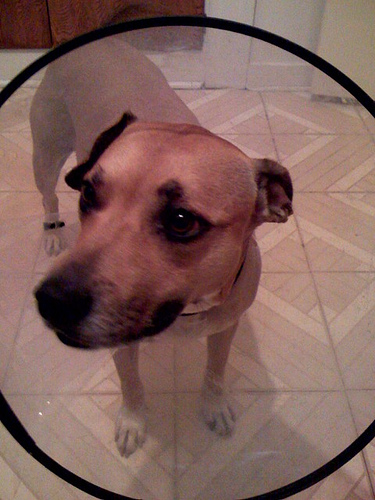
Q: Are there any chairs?
A: No, there are no chairs.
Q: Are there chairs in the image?
A: No, there are no chairs.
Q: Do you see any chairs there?
A: No, there are no chairs.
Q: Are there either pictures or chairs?
A: No, there are no chairs or pictures.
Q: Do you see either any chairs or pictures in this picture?
A: No, there are no chairs or pictures.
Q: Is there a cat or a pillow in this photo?
A: No, there are no cats or pillows.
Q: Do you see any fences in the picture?
A: No, there are no fences.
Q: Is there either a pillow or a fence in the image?
A: No, there are no fences or pillows.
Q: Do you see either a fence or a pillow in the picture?
A: No, there are no fences or pillows.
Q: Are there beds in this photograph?
A: No, there are no beds.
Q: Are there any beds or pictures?
A: No, there are no beds or pictures.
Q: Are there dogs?
A: Yes, there is a dog.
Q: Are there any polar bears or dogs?
A: Yes, there is a dog.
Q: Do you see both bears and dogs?
A: No, there is a dog but no bears.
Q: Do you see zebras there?
A: No, there are no zebras.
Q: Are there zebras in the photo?
A: No, there are no zebras.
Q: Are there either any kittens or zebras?
A: No, there are no zebras or kittens.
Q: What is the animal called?
A: The animal is a dog.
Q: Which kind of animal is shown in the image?
A: The animal is a dog.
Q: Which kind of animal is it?
A: The animal is a dog.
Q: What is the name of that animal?
A: That is a dog.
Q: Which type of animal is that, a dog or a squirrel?
A: That is a dog.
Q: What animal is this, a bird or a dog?
A: This is a dog.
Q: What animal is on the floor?
A: The dog is on the floor.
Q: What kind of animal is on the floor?
A: The animal is a dog.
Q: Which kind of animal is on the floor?
A: The animal is a dog.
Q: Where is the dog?
A: The dog is on the floor.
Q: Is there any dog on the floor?
A: Yes, there is a dog on the floor.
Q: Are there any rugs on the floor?
A: No, there is a dog on the floor.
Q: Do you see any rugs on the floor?
A: No, there is a dog on the floor.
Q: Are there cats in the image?
A: No, there are no cats.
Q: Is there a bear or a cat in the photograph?
A: No, there are no cats or bears.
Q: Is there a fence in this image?
A: No, there are no fences.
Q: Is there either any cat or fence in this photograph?
A: No, there are no fences or cats.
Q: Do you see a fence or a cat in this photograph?
A: No, there are no fences or cats.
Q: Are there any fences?
A: No, there are no fences.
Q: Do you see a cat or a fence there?
A: No, there are no fences or cats.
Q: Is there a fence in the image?
A: No, there are no fences.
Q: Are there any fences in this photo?
A: No, there are no fences.